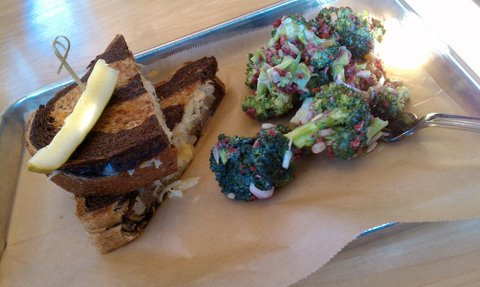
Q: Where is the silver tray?
A: On the table.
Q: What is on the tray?
A: Multi colored bread.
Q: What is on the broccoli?
A: Red peppers.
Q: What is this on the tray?
A: Cake.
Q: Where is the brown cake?
A: On the tray.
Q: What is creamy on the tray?
A: The broccoli.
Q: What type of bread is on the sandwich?
A: Rye.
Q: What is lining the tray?
A: Brown wax paper.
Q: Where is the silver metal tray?
A: Under the food.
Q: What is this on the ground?
A: It's paper.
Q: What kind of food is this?
A: Ice cream.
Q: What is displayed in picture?
A: Pieces of cake.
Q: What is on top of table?
A: Cafeteria tray.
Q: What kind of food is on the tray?
A: Sandwich.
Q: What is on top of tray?
A: Parchment paper.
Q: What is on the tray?
A: Vegetable salad.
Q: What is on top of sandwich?
A: Pickle slice.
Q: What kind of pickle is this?
A: Small.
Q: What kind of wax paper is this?
A: White.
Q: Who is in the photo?
A: Nobody.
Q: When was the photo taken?
A: Daytime.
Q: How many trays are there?
A: One.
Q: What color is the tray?
A: Silver.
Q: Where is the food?
A: On the tray.